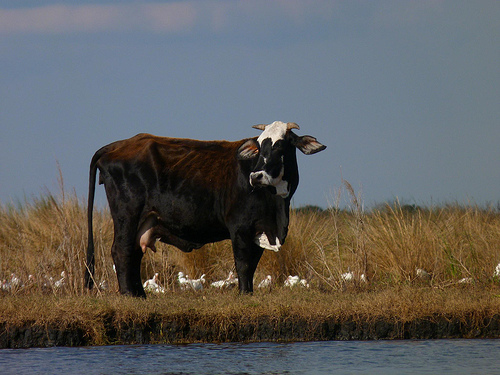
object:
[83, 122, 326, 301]
cow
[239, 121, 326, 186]
head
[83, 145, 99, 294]
tail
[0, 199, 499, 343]
grass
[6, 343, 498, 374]
water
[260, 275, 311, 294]
trash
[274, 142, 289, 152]
eye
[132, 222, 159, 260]
utters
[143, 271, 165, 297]
birds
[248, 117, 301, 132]
horns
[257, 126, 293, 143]
white spot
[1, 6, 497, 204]
sky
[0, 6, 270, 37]
clouds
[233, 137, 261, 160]
ear